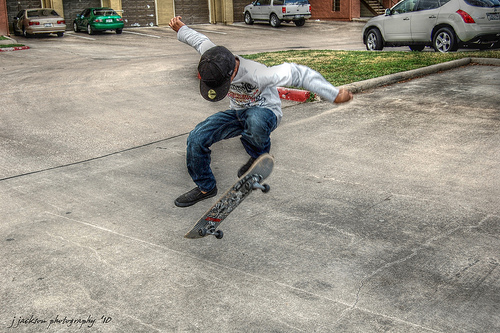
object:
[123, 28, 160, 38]
line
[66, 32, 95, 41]
line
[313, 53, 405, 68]
grass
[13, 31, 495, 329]
courtyard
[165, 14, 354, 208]
boy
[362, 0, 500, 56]
car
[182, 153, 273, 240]
skateboard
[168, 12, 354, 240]
snap back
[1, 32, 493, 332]
lot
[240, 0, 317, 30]
suv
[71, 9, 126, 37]
car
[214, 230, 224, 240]
wheel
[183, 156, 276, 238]
board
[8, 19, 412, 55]
parking area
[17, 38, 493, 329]
floor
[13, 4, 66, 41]
vehicles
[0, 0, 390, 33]
building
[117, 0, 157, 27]
door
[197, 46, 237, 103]
cap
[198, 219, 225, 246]
truck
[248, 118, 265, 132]
knee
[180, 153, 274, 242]
skate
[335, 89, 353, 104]
hand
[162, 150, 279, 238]
trick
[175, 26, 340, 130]
shirt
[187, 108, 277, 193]
jeans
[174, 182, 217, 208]
shoe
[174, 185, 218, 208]
foot